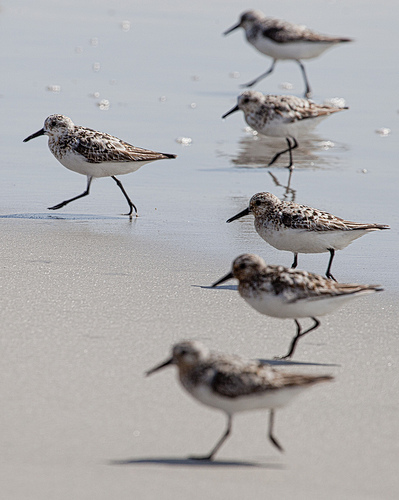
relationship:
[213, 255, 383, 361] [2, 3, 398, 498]
bird standing in sand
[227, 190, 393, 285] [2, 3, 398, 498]
bird standing in sand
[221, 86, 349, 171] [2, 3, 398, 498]
bird standing in sand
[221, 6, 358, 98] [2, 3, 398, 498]
bird standing in sand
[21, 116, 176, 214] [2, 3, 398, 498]
bird standing in sand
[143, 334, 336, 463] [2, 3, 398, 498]
bird standing in sand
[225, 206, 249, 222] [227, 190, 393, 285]
beak on bird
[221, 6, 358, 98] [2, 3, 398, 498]
bird running across sand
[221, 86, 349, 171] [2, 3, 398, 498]
bird running across sand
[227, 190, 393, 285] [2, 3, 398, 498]
bird running across sand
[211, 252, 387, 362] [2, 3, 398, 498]
bird running across sand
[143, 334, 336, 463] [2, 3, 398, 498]
bird running across sand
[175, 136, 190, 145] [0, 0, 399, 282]
bubble in sea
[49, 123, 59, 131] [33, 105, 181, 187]
eye on bird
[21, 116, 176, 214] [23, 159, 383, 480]
bird standing in sand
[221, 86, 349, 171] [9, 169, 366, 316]
bird standing in sand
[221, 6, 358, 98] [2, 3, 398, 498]
bird in sand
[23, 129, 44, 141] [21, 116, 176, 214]
beak on bird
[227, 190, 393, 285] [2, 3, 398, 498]
bird in sand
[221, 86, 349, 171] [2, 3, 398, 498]
bird in sand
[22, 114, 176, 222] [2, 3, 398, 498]
bird in sand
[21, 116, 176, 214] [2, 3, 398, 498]
bird on sand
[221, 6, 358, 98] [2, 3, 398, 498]
bird on sand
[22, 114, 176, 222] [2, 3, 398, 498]
bird running on sand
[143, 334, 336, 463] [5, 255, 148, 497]
bird standing in sand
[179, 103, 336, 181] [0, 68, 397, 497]
bird standing in sand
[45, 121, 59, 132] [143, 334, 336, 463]
eye on bird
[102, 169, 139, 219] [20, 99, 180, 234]
leg on bird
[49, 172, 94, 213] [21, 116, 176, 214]
leg on bird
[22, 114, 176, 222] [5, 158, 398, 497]
bird on sand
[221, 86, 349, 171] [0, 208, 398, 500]
bird on sand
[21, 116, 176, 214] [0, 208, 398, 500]
bird on sand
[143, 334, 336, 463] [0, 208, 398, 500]
bird on sand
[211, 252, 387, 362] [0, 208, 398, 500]
bird on sand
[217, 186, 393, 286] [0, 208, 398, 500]
bird on sand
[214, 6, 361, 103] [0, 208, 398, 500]
bird on sand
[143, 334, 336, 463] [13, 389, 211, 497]
bird on sand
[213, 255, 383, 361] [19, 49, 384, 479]
bird on sand